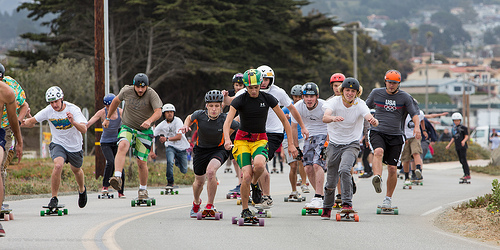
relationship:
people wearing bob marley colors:
[222, 69, 299, 222] [231, 130, 265, 165]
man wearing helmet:
[330, 82, 365, 207] [384, 69, 402, 82]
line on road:
[86, 223, 133, 239] [163, 229, 199, 243]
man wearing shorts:
[330, 82, 365, 207] [109, 125, 153, 152]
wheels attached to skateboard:
[198, 212, 222, 222] [243, 215, 264, 222]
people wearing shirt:
[222, 69, 299, 222] [332, 105, 353, 140]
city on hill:
[425, 64, 482, 91] [386, 41, 410, 53]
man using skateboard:
[330, 82, 365, 207] [243, 215, 264, 222]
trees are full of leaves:
[123, 9, 218, 81] [217, 26, 239, 41]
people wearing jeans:
[222, 69, 299, 222] [64, 153, 84, 164]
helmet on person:
[384, 69, 402, 82] [112, 70, 152, 209]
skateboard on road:
[243, 215, 264, 222] [163, 229, 199, 243]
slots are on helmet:
[141, 76, 145, 80] [384, 69, 402, 82]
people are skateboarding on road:
[54, 75, 398, 206] [163, 229, 199, 243]